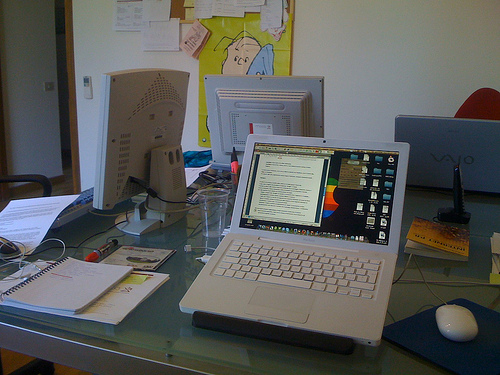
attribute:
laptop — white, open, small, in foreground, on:
[218, 132, 408, 351]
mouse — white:
[425, 302, 478, 342]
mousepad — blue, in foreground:
[397, 291, 498, 367]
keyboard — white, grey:
[220, 224, 381, 296]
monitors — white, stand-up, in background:
[93, 71, 331, 214]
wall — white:
[304, 7, 498, 82]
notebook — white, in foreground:
[31, 257, 106, 315]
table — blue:
[5, 174, 490, 360]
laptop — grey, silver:
[381, 85, 491, 186]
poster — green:
[200, 10, 287, 144]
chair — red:
[462, 67, 498, 116]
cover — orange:
[418, 218, 469, 263]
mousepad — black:
[0, 256, 30, 273]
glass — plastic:
[183, 179, 232, 234]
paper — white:
[2, 203, 67, 269]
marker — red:
[85, 238, 121, 267]